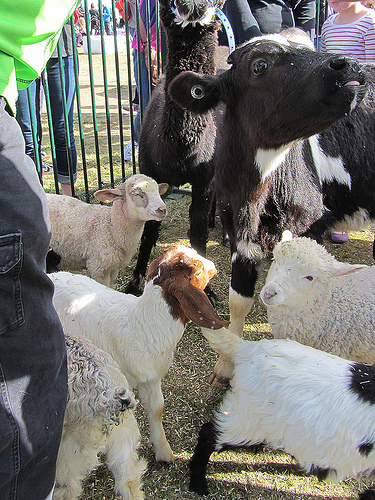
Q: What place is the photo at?
A: It is at the zoo.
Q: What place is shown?
A: It is a zoo.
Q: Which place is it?
A: It is a zoo.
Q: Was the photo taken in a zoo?
A: Yes, it was taken in a zoo.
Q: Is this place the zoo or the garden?
A: It is the zoo.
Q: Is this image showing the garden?
A: No, the picture is showing the zoo.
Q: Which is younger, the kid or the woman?
A: The kid is younger than the woman.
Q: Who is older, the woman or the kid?
A: The woman is older than the kid.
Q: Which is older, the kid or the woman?
A: The woman is older than the kid.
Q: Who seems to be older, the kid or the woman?
A: The woman is older than the kid.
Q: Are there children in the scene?
A: Yes, there is a child.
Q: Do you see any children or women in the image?
A: Yes, there is a child.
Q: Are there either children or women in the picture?
A: Yes, there is a child.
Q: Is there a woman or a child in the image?
A: Yes, there is a child.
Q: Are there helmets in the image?
A: No, there are no helmets.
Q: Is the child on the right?
A: Yes, the child is on the right of the image.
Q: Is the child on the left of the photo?
A: No, the child is on the right of the image.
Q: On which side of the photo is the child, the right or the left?
A: The child is on the right of the image.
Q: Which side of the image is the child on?
A: The child is on the right of the image.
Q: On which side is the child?
A: The child is on the right of the image.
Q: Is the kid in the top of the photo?
A: Yes, the kid is in the top of the image.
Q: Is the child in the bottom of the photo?
A: No, the child is in the top of the image.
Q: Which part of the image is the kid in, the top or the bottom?
A: The kid is in the top of the image.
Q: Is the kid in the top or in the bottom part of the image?
A: The kid is in the top of the image.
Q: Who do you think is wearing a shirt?
A: The kid is wearing a shirt.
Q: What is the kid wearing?
A: The kid is wearing a shirt.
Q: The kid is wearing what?
A: The kid is wearing a shirt.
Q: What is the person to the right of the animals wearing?
A: The kid is wearing a shirt.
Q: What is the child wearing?
A: The kid is wearing a shirt.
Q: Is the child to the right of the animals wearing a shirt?
A: Yes, the child is wearing a shirt.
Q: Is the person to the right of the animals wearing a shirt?
A: Yes, the child is wearing a shirt.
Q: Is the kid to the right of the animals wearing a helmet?
A: No, the child is wearing a shirt.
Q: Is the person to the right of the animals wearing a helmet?
A: No, the child is wearing a shirt.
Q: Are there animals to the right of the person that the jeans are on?
A: Yes, there is an animal to the right of the person.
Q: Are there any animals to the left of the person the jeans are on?
A: No, the animal is to the right of the person.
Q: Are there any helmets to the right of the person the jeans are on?
A: No, there is an animal to the right of the person.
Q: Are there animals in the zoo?
A: Yes, there is an animal in the zoo.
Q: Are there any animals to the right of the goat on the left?
A: Yes, there is an animal to the right of the goat.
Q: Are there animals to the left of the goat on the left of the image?
A: No, the animal is to the right of the goat.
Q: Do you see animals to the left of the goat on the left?
A: No, the animal is to the right of the goat.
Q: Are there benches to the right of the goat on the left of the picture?
A: No, there is an animal to the right of the goat.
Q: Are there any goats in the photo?
A: Yes, there is a goat.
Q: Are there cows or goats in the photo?
A: Yes, there is a goat.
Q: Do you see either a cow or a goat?
A: Yes, there is a goat.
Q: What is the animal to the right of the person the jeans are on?
A: The animal is a goat.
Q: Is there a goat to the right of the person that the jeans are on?
A: Yes, there is a goat to the right of the person.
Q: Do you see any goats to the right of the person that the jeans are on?
A: Yes, there is a goat to the right of the person.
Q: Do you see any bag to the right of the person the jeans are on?
A: No, there is a goat to the right of the person.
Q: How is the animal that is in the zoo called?
A: The animal is a goat.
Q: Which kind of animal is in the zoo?
A: The animal is a goat.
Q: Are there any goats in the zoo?
A: Yes, there is a goat in the zoo.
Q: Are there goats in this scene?
A: Yes, there is a goat.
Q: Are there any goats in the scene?
A: Yes, there is a goat.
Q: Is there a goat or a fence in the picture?
A: Yes, there is a goat.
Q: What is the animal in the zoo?
A: The animal is a goat.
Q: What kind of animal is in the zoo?
A: The animal is a goat.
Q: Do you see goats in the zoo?
A: Yes, there is a goat in the zoo.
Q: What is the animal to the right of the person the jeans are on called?
A: The animal is a goat.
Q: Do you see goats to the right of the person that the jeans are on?
A: Yes, there is a goat to the right of the person.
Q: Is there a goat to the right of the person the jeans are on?
A: Yes, there is a goat to the right of the person.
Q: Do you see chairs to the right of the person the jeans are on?
A: No, there is a goat to the right of the person.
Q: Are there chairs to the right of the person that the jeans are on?
A: No, there is a goat to the right of the person.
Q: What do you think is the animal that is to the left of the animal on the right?
A: The animal is a goat.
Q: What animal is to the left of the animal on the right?
A: The animal is a goat.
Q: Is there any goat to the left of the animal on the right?
A: Yes, there is a goat to the left of the animal.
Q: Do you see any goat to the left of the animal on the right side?
A: Yes, there is a goat to the left of the animal.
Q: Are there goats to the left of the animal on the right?
A: Yes, there is a goat to the left of the animal.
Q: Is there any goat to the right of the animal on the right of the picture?
A: No, the goat is to the left of the animal.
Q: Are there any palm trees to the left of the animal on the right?
A: No, there is a goat to the left of the animal.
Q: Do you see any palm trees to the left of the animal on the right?
A: No, there is a goat to the left of the animal.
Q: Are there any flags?
A: No, there are no flags.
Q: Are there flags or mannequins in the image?
A: No, there are no flags or mannequins.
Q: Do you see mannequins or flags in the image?
A: No, there are no flags or mannequins.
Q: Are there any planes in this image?
A: No, there are no planes.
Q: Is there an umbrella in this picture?
A: No, there are no umbrellas.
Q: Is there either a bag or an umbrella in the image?
A: No, there are no umbrellas or bags.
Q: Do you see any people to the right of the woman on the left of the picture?
A: Yes, there are people to the right of the woman.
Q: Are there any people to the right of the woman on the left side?
A: Yes, there are people to the right of the woman.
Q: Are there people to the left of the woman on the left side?
A: No, the people are to the right of the woman.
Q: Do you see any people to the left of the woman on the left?
A: No, the people are to the right of the woman.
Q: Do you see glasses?
A: No, there are no glasses.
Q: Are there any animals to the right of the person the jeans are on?
A: Yes, there are animals to the right of the person.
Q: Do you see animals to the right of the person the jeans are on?
A: Yes, there are animals to the right of the person.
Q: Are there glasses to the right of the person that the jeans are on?
A: No, there are animals to the right of the person.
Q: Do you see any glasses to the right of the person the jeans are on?
A: No, there are animals to the right of the person.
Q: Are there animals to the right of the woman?
A: Yes, there are animals to the right of the woman.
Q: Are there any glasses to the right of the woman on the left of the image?
A: No, there are animals to the right of the woman.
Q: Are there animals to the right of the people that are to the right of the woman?
A: Yes, there are animals to the right of the people.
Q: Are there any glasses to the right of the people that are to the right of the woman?
A: No, there are animals to the right of the people.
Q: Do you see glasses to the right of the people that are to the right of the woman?
A: No, there are animals to the right of the people.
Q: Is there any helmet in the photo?
A: No, there are no helmets.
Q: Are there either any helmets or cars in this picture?
A: No, there are no helmets or cars.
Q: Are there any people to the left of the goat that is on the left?
A: Yes, there is a person to the left of the goat.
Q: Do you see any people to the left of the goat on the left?
A: Yes, there is a person to the left of the goat.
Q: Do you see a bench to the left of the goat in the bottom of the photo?
A: No, there is a person to the left of the goat.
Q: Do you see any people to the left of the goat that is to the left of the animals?
A: Yes, there is a person to the left of the goat.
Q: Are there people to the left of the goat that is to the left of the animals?
A: Yes, there is a person to the left of the goat.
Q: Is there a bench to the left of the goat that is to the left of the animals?
A: No, there is a person to the left of the goat.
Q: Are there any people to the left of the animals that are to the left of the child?
A: Yes, there is a person to the left of the animals.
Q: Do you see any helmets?
A: No, there are no helmets.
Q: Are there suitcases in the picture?
A: No, there are no suitcases.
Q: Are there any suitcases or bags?
A: No, there are no suitcases or bags.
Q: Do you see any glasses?
A: No, there are no glasses.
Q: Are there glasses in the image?
A: No, there are no glasses.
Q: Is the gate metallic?
A: Yes, the gate is metallic.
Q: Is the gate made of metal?
A: Yes, the gate is made of metal.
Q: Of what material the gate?
A: The gate is made of metal.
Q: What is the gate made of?
A: The gate is made of metal.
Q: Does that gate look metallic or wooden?
A: The gate is metallic.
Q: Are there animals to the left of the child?
A: Yes, there are animals to the left of the child.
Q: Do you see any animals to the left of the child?
A: Yes, there are animals to the left of the child.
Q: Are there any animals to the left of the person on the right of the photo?
A: Yes, there are animals to the left of the child.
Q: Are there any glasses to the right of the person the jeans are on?
A: No, there are animals to the right of the person.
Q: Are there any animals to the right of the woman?
A: Yes, there are animals to the right of the woman.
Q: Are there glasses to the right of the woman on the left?
A: No, there are animals to the right of the woman.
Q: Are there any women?
A: Yes, there is a woman.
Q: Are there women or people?
A: Yes, there is a woman.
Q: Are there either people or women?
A: Yes, there is a woman.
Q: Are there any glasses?
A: No, there are no glasses.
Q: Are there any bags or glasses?
A: No, there are no glasses or bags.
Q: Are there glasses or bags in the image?
A: No, there are no glasses or bags.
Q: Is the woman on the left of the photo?
A: Yes, the woman is on the left of the image.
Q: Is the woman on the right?
A: No, the woman is on the left of the image.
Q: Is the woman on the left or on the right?
A: The woman is on the left of the image.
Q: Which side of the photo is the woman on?
A: The woman is on the left of the image.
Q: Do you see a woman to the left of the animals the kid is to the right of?
A: Yes, there is a woman to the left of the animals.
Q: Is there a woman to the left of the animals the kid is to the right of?
A: Yes, there is a woman to the left of the animals.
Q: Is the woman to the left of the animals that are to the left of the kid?
A: Yes, the woman is to the left of the animals.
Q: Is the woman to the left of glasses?
A: No, the woman is to the left of the animals.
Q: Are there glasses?
A: No, there are no glasses.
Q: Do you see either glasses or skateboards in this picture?
A: No, there are no glasses or skateboards.